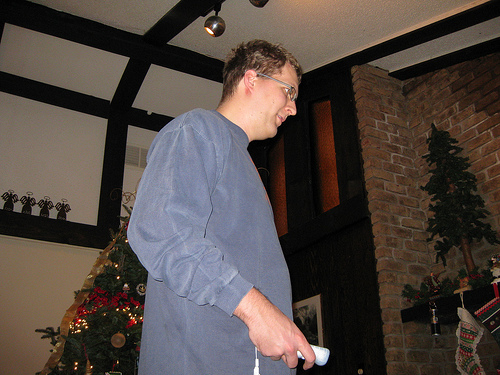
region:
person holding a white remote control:
[125, 34, 342, 374]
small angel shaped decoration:
[50, 193, 77, 225]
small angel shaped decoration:
[37, 193, 52, 218]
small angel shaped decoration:
[15, 187, 37, 217]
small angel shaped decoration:
[0, 185, 20, 221]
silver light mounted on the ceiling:
[198, 12, 228, 42]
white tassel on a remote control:
[249, 346, 263, 374]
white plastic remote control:
[236, 330, 334, 374]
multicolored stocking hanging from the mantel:
[445, 286, 492, 374]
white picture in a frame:
[287, 290, 334, 352]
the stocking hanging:
[455, 289, 486, 372]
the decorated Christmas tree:
[34, 180, 148, 373]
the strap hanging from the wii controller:
[253, 345, 259, 373]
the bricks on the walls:
[350, 40, 498, 373]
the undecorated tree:
[420, 123, 498, 275]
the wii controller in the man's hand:
[296, 343, 329, 365]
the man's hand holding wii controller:
[248, 305, 316, 370]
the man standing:
[125, 38, 315, 373]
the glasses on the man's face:
[245, 70, 297, 102]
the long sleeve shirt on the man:
[127, 108, 297, 373]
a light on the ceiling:
[210, 14, 222, 32]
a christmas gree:
[50, 213, 163, 370]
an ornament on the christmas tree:
[108, 335, 125, 346]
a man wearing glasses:
[136, 43, 333, 373]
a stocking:
[452, 308, 489, 374]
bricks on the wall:
[363, 85, 475, 240]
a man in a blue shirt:
[157, 43, 334, 371]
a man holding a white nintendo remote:
[145, 53, 317, 369]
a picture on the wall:
[295, 301, 330, 333]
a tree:
[423, 124, 483, 264]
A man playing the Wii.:
[107, 31, 372, 362]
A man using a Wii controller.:
[105, 29, 393, 373]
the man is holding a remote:
[91, 20, 380, 369]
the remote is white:
[220, 302, 337, 367]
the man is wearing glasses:
[222, 40, 312, 146]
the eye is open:
[255, 65, 297, 102]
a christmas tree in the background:
[41, 165, 146, 370]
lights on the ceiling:
[170, 0, 286, 42]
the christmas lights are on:
[50, 200, 145, 365]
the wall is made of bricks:
[360, 46, 490, 156]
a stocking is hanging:
[425, 270, 490, 365]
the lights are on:
[146, 0, 276, 46]